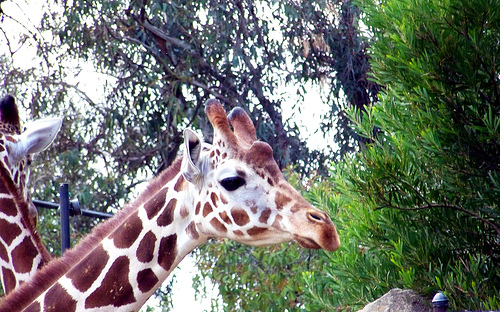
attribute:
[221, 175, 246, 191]
eye — black